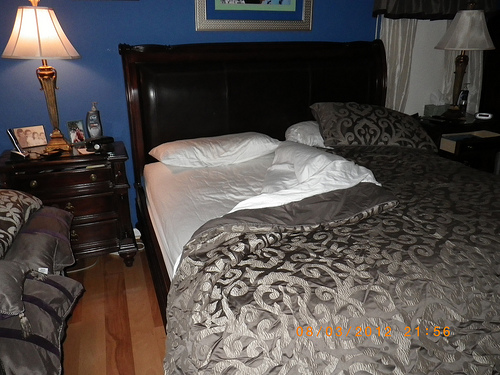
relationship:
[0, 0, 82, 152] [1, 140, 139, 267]
light on table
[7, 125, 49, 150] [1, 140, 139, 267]
picture on table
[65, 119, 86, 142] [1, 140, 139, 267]
picture on table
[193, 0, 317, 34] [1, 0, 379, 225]
frame on wall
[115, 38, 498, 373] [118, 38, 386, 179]
bed has headboard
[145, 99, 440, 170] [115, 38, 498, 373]
pillows on bed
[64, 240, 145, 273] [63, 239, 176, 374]
wire on floor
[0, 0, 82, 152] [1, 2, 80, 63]
light has shade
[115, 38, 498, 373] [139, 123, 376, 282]
bed has linens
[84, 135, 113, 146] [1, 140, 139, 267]
phone on table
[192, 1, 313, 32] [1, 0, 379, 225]
frame hanging on wall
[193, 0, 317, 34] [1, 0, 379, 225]
frame hanging on wall